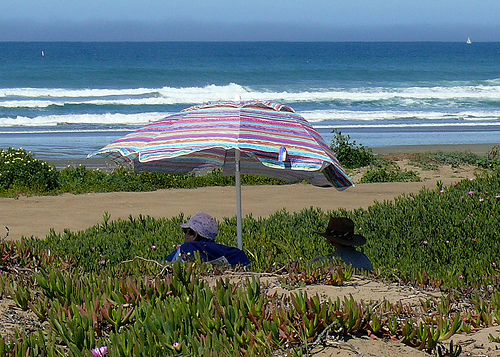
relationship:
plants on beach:
[0, 132, 422, 189] [2, 136, 495, 348]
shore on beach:
[5, 117, 490, 169] [2, 136, 495, 348]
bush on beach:
[0, 140, 59, 197] [2, 136, 495, 348]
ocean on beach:
[5, 4, 499, 129] [2, 136, 495, 348]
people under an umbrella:
[162, 209, 374, 281] [93, 98, 355, 276]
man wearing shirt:
[300, 214, 375, 281] [167, 242, 247, 267]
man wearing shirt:
[300, 214, 375, 281] [315, 248, 373, 275]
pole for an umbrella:
[233, 148, 249, 261] [93, 98, 355, 276]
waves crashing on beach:
[3, 82, 498, 137] [2, 136, 495, 348]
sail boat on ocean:
[462, 33, 474, 45] [5, 4, 499, 129]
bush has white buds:
[0, 140, 59, 197] [4, 144, 31, 165]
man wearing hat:
[300, 214, 375, 281] [184, 211, 223, 240]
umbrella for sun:
[93, 98, 355, 276] [2, 0, 496, 10]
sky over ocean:
[3, 4, 499, 45] [5, 4, 499, 129]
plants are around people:
[2, 174, 499, 352] [162, 209, 374, 281]